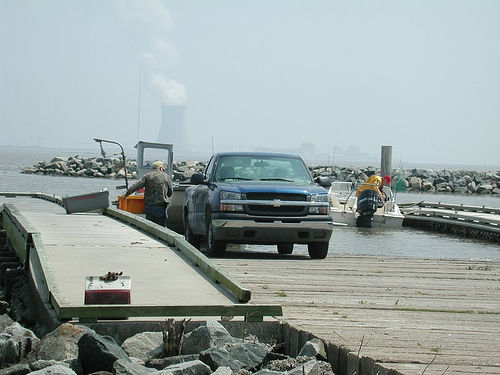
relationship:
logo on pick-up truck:
[265, 196, 288, 209] [182, 150, 333, 260]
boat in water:
[337, 172, 409, 222] [347, 226, 372, 248]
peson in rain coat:
[354, 152, 388, 218] [359, 174, 390, 198]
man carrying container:
[123, 160, 174, 225] [114, 184, 142, 219]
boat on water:
[327, 172, 409, 229] [372, 229, 428, 259]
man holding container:
[134, 147, 173, 222] [119, 191, 156, 224]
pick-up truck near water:
[182, 150, 333, 260] [343, 219, 381, 249]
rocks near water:
[52, 146, 437, 187] [32, 169, 64, 189]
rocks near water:
[25, 139, 232, 192] [17, 167, 39, 192]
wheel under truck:
[205, 224, 229, 250] [202, 158, 323, 252]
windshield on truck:
[214, 148, 314, 185] [189, 155, 326, 252]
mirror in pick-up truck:
[252, 159, 272, 168] [182, 150, 333, 260]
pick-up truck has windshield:
[182, 150, 333, 260] [215, 155, 314, 183]